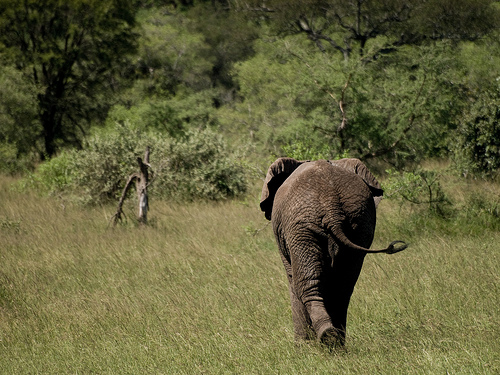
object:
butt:
[287, 172, 370, 236]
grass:
[399, 200, 490, 312]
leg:
[292, 233, 335, 323]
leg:
[329, 243, 372, 331]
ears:
[329, 156, 385, 199]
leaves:
[191, 44, 208, 72]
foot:
[316, 323, 346, 353]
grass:
[30, 225, 272, 348]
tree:
[0, 0, 139, 159]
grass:
[23, 180, 495, 368]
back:
[286, 159, 364, 185]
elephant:
[259, 157, 408, 354]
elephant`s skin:
[271, 160, 376, 339]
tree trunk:
[135, 152, 155, 224]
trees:
[133, 1, 500, 165]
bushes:
[0, 96, 346, 204]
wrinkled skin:
[279, 177, 331, 306]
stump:
[109, 145, 158, 229]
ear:
[259, 156, 301, 229]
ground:
[39, 279, 204, 369]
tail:
[326, 217, 408, 255]